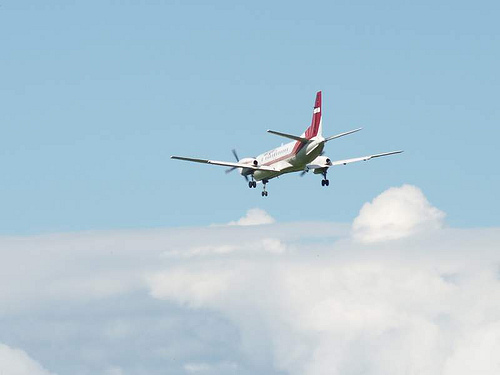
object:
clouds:
[0, 185, 499, 374]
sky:
[0, 0, 500, 89]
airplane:
[169, 90, 403, 196]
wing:
[170, 155, 273, 172]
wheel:
[248, 181, 252, 188]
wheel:
[261, 191, 265, 196]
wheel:
[322, 180, 325, 186]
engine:
[240, 159, 258, 176]